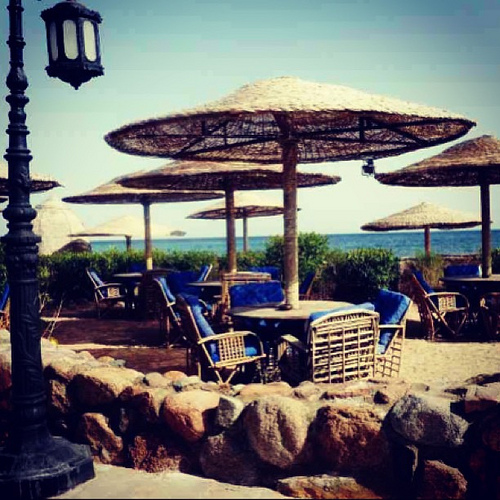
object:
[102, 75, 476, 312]
umbrella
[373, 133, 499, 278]
umbrella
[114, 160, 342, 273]
umbrella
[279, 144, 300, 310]
pole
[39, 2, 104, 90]
lamp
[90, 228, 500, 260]
ocean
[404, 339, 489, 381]
sand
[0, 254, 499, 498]
cabana area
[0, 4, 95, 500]
pole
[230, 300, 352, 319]
table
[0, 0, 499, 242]
sky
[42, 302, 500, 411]
beach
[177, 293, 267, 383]
chairs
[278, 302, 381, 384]
chairs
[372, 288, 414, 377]
chairs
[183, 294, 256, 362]
cushion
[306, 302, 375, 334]
cushion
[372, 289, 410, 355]
cushion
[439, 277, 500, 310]
table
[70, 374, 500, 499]
wall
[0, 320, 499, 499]
rocks